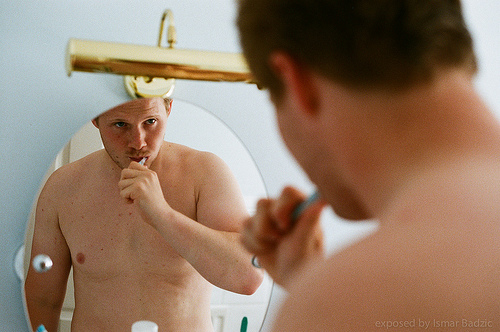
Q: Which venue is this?
A: This is a bathroom.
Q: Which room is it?
A: It is a bathroom.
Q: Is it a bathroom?
A: Yes, it is a bathroom.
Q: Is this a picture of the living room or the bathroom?
A: It is showing the bathroom.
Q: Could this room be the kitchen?
A: No, it is the bathroom.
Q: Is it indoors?
A: Yes, it is indoors.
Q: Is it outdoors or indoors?
A: It is indoors.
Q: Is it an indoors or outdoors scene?
A: It is indoors.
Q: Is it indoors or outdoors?
A: It is indoors.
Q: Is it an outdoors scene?
A: No, it is indoors.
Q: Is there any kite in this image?
A: No, there are no kites.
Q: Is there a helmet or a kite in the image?
A: No, there are no kites or helmets.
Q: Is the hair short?
A: Yes, the hair is short.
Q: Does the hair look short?
A: Yes, the hair is short.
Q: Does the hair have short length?
A: Yes, the hair is short.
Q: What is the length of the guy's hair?
A: The hair is short.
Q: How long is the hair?
A: The hair is short.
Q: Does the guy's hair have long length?
A: No, the hair is short.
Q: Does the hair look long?
A: No, the hair is short.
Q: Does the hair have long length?
A: No, the hair is short.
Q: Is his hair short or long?
A: The hair is short.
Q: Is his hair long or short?
A: The hair is short.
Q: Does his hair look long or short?
A: The hair is short.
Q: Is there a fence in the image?
A: No, there are no fences.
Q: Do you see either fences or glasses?
A: No, there are no fences or glasses.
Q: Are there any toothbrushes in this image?
A: Yes, there is a toothbrush.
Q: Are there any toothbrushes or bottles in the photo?
A: Yes, there is a toothbrush.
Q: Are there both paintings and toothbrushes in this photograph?
A: No, there is a toothbrush but no paintings.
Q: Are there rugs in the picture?
A: No, there are no rugs.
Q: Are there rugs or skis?
A: No, there are no rugs or skis.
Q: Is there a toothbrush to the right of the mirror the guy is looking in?
A: Yes, there is a toothbrush to the right of the mirror.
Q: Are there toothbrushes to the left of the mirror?
A: No, the toothbrush is to the right of the mirror.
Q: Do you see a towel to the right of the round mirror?
A: No, there is a toothbrush to the right of the mirror.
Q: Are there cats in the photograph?
A: No, there are no cats.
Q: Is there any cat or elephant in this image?
A: No, there are no cats or elephants.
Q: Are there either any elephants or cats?
A: No, there are no cats or elephants.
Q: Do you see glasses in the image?
A: No, there are no glasses.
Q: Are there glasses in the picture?
A: No, there are no glasses.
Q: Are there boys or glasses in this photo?
A: No, there are no glasses or boys.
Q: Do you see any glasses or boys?
A: No, there are no glasses or boys.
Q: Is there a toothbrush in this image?
A: Yes, there is a toothbrush.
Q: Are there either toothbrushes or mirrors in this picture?
A: Yes, there is a toothbrush.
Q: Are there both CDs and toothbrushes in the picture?
A: No, there is a toothbrush but no cds.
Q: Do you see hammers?
A: No, there are no hammers.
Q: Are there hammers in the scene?
A: No, there are no hammers.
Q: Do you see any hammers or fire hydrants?
A: No, there are no hammers or fire hydrants.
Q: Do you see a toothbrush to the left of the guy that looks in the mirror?
A: Yes, there is a toothbrush to the left of the guy.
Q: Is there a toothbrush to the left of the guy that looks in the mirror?
A: Yes, there is a toothbrush to the left of the guy.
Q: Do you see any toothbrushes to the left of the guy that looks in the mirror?
A: Yes, there is a toothbrush to the left of the guy.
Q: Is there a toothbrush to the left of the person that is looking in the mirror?
A: Yes, there is a toothbrush to the left of the guy.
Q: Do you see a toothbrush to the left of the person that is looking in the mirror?
A: Yes, there is a toothbrush to the left of the guy.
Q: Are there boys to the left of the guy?
A: No, there is a toothbrush to the left of the guy.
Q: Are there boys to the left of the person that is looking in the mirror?
A: No, there is a toothbrush to the left of the guy.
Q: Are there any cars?
A: No, there are no cars.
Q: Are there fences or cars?
A: No, there are no cars or fences.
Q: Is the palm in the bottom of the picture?
A: Yes, the palm is in the bottom of the image.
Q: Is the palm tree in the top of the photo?
A: No, the palm tree is in the bottom of the image.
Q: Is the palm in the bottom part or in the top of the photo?
A: The palm is in the bottom of the image.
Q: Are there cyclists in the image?
A: No, there are no cyclists.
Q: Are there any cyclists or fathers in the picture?
A: No, there are no cyclists or fathers.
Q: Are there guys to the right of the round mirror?
A: Yes, there is a guy to the right of the mirror.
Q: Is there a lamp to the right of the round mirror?
A: No, there is a guy to the right of the mirror.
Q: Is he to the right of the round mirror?
A: Yes, the guy is to the right of the mirror.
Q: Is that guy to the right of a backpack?
A: No, the guy is to the right of the mirror.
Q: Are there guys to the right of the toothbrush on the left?
A: Yes, there is a guy to the right of the toothbrush.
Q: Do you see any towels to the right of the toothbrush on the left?
A: No, there is a guy to the right of the toothbrush.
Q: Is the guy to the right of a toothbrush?
A: Yes, the guy is to the right of a toothbrush.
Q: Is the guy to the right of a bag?
A: No, the guy is to the right of a toothbrush.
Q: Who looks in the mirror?
A: The guy looks in the mirror.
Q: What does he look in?
A: The guy looks in the mirror.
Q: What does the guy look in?
A: The guy looks in the mirror.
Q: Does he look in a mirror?
A: Yes, the guy looks in a mirror.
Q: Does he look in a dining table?
A: No, the guy looks in a mirror.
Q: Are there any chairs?
A: No, there are no chairs.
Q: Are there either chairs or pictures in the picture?
A: No, there are no chairs or pictures.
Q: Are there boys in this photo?
A: No, there are no boys.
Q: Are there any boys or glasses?
A: No, there are no boys or glasses.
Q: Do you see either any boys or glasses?
A: No, there are no boys or glasses.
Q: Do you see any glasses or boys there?
A: No, there are no boys or glasses.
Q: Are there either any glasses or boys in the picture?
A: No, there are no boys or glasses.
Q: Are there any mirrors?
A: Yes, there is a mirror.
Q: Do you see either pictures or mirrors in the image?
A: Yes, there is a mirror.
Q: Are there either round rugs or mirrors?
A: Yes, there is a round mirror.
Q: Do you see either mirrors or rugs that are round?
A: Yes, the mirror is round.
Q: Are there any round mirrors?
A: Yes, there is a round mirror.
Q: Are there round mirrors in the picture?
A: Yes, there is a round mirror.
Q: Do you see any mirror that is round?
A: Yes, there is a mirror that is round.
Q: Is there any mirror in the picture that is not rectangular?
A: Yes, there is a round mirror.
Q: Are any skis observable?
A: No, there are no skis.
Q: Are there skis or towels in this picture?
A: No, there are no skis or towels.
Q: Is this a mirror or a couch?
A: This is a mirror.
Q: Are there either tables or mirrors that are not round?
A: No, there is a mirror but it is round.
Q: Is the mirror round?
A: Yes, the mirror is round.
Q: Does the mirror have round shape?
A: Yes, the mirror is round.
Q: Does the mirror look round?
A: Yes, the mirror is round.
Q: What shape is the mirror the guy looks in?
A: The mirror is round.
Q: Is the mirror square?
A: No, the mirror is round.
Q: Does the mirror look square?
A: No, the mirror is round.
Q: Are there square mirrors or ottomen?
A: No, there is a mirror but it is round.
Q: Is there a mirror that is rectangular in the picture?
A: No, there is a mirror but it is round.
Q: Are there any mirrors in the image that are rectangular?
A: No, there is a mirror but it is round.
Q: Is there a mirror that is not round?
A: No, there is a mirror but it is round.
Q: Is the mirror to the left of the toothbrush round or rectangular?
A: The mirror is round.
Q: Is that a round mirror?
A: Yes, that is a round mirror.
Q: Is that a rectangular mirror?
A: No, that is a round mirror.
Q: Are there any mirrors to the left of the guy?
A: Yes, there is a mirror to the left of the guy.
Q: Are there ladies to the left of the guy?
A: No, there is a mirror to the left of the guy.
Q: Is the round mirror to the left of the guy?
A: Yes, the mirror is to the left of the guy.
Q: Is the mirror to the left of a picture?
A: No, the mirror is to the left of the guy.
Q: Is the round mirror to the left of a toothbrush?
A: Yes, the mirror is to the left of a toothbrush.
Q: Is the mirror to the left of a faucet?
A: No, the mirror is to the left of a toothbrush.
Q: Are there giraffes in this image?
A: No, there are no giraffes.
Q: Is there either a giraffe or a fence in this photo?
A: No, there are no giraffes or fences.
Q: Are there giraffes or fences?
A: No, there are no giraffes or fences.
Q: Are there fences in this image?
A: No, there are no fences.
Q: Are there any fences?
A: No, there are no fences.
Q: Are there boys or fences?
A: No, there are no fences or boys.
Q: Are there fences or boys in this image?
A: No, there are no fences or boys.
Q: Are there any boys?
A: No, there are no boys.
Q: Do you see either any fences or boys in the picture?
A: No, there are no boys or fences.